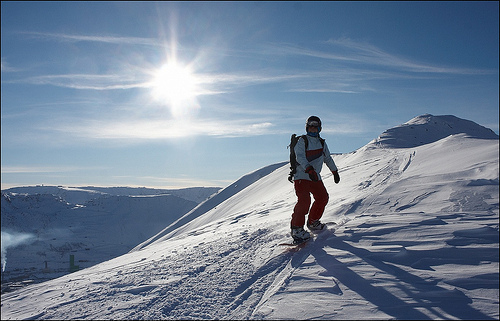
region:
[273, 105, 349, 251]
snowboarder on snow board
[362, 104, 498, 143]
peak of mountain top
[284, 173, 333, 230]
red pants of the snowboarder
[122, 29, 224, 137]
bright shining sun in the sky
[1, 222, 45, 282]
smoke from down in valley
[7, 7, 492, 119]
blue sky with few wispy clouds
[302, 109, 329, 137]
snow boarders head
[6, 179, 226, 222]
mountains in distance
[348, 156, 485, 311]
white snow on the side of mountain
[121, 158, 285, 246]
snow covered ridge of mountain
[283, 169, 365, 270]
a person wearing red pants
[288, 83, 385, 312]
a person hiking through snow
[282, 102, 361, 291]
a person hiking up a mountain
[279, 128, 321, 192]
a person carrying a backpack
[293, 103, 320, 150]
a person wearing a hat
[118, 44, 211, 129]
the sun shining over the mountains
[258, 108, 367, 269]
person standing on snow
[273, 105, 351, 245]
a person standing on a mountain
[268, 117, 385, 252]
a person standing under the sun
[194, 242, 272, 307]
snow marks engraved in the snow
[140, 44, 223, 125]
sun bright in the sky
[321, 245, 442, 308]
shadow of the man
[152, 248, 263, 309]
snow on the mountain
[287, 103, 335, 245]
man in the snow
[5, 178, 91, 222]
mountain in the distance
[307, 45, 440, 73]
wispy clouds in the sky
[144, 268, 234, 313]
tracks in the snow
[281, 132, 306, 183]
backpack on the back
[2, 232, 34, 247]
smoke in the sky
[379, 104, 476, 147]
peak of the mountain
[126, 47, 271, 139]
The sun is shining in the sky.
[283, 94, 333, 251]
A person on top of the hill.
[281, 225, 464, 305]
a reflection in the snow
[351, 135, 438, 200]
Tracks in the snow.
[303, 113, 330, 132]
The man is wearing a red cap.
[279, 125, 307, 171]
The man has a backpack on back.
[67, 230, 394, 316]
The snow is white.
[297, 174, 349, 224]
The man is wearing red pants.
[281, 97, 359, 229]
The man is hiking in the snow.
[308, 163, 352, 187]
The man is wearing gloves.